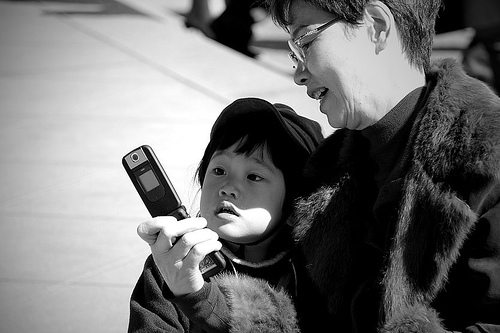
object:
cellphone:
[122, 145, 228, 279]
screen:
[138, 169, 160, 193]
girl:
[128, 97, 328, 332]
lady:
[289, 0, 500, 332]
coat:
[272, 56, 498, 330]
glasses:
[287, 16, 346, 69]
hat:
[210, 98, 327, 155]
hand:
[137, 216, 224, 297]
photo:
[0, 0, 498, 330]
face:
[199, 139, 281, 241]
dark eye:
[211, 167, 226, 175]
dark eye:
[247, 174, 264, 182]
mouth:
[214, 202, 240, 220]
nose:
[218, 183, 241, 199]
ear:
[363, 0, 395, 55]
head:
[269, 0, 446, 130]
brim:
[209, 99, 310, 160]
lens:
[133, 154, 139, 160]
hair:
[192, 116, 311, 204]